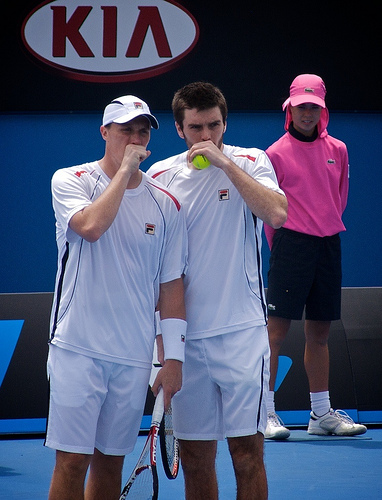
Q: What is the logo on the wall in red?
A: Kia.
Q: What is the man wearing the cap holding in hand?
A: Racket.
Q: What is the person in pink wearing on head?
A: Cap.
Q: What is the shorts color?
A: White.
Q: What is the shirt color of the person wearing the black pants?
A: Pink.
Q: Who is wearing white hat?
A: Man on left.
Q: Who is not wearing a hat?
A: Person in center.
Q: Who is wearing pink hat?
A: Person on right.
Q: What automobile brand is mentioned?
A: Kia.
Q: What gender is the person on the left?
A: Male.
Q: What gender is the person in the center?
A: Male.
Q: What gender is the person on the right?
A: Female.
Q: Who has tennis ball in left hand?
A: Center person.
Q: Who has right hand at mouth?
A: Person on left.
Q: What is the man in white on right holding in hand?
A: Tennis ball.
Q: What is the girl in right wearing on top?
A: Pink shirt.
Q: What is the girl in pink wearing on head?
A: Hat.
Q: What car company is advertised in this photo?
A: Kia.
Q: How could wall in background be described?
A: Blue and black.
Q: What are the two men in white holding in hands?
A: Tennis racket.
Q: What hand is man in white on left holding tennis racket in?
A: Left.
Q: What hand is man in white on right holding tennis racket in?
A: Right.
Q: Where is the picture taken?
A: Tennis court.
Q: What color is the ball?
A: Yellow.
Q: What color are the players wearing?
A: White.